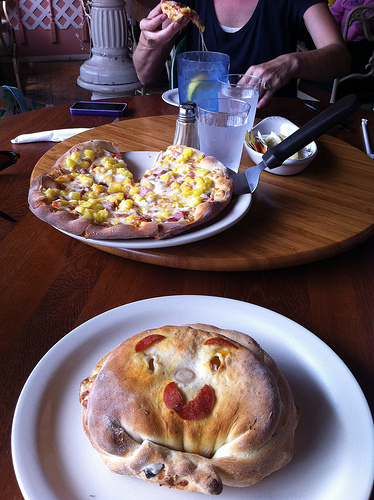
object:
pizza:
[27, 139, 234, 241]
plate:
[47, 147, 253, 249]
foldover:
[77, 324, 301, 498]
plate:
[10, 294, 372, 500]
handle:
[260, 93, 365, 170]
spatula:
[227, 93, 361, 200]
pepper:
[172, 102, 200, 151]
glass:
[196, 97, 251, 174]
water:
[195, 120, 246, 175]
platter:
[29, 112, 372, 272]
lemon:
[186, 72, 220, 114]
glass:
[175, 51, 231, 116]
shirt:
[166, 1, 330, 121]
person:
[130, 0, 352, 108]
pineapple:
[121, 200, 138, 210]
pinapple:
[190, 197, 201, 205]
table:
[1, 93, 373, 499]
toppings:
[53, 142, 210, 223]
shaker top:
[177, 101, 198, 124]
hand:
[138, 2, 192, 49]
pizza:
[160, 0, 209, 33]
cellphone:
[68, 100, 130, 116]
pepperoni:
[163, 382, 221, 420]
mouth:
[170, 381, 211, 405]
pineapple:
[106, 181, 124, 193]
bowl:
[246, 115, 317, 177]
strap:
[3, 84, 29, 113]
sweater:
[327, 0, 374, 40]